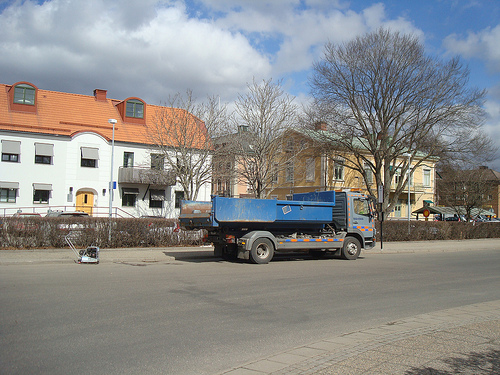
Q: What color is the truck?
A: Blue.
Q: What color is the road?
A: Grey.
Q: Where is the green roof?
A: On the yellow building.